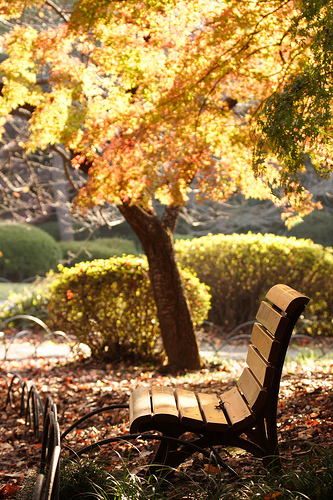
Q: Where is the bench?
A: Under the branches.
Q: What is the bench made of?
A: Wood.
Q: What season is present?
A: Autumn.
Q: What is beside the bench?
A: A tree.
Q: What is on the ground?
A: Leaves.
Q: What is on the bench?
A: A single leaf.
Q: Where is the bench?
A: In the park.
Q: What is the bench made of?
A: Wood.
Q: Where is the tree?
A: Behind the bench.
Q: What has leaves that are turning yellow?
A: The tree.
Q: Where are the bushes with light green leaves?
A: Behind the tree.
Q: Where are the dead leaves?
A: On the ground around the bench.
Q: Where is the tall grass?
A: In front of the bench.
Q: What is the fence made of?
A: Looped wires.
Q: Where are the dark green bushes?
A: Behind the light green bushes.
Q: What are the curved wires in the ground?
A: A fence.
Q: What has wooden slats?
A: The bench has wooden slats.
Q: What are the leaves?
A: The leaves of the tree are yellow and orange.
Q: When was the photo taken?
A: Daytime.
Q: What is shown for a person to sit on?
A: Bench.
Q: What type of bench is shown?
A: Wooden.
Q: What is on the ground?
A: Leaves.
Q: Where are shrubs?
A: Behind the tree.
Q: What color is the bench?
A: Brown.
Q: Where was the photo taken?
A: In a park.